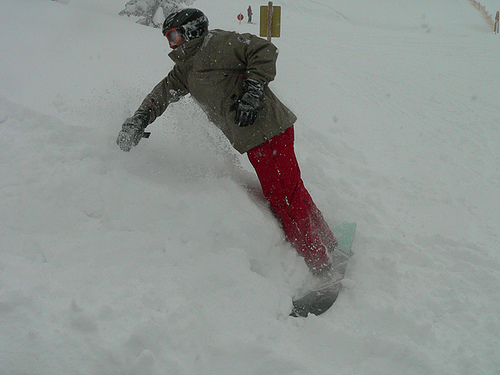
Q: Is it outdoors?
A: Yes, it is outdoors.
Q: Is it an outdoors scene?
A: Yes, it is outdoors.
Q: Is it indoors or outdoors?
A: It is outdoors.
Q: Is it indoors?
A: No, it is outdoors.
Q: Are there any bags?
A: No, there are no bags.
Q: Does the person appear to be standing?
A: Yes, the person is standing.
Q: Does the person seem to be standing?
A: Yes, the person is standing.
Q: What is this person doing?
A: The person is standing.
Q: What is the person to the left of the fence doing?
A: The person is standing.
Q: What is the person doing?
A: The person is standing.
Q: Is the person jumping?
A: No, the person is standing.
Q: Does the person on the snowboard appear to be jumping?
A: No, the person is standing.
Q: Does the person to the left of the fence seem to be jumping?
A: No, the person is standing.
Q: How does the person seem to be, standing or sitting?
A: The person is standing.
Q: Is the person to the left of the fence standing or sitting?
A: The person is standing.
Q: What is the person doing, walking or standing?
A: The person is standing.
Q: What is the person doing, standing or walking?
A: The person is standing.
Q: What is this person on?
A: The person is on the snow board.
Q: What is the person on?
A: The person is on the snow board.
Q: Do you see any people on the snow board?
A: Yes, there is a person on the snow board.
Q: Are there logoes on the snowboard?
A: No, there is a person on the snowboard.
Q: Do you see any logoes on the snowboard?
A: No, there is a person on the snowboard.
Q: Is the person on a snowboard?
A: Yes, the person is on a snowboard.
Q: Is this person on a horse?
A: No, the person is on a snowboard.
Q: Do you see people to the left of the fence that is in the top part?
A: Yes, there is a person to the left of the fence.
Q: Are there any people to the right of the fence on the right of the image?
A: No, the person is to the left of the fence.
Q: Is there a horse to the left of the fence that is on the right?
A: No, there is a person to the left of the fence.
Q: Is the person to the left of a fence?
A: Yes, the person is to the left of a fence.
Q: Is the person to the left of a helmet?
A: No, the person is to the left of a fence.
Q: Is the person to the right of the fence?
A: No, the person is to the left of the fence.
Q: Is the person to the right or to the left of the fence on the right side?
A: The person is to the left of the fence.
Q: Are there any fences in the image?
A: Yes, there is a fence.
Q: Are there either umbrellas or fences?
A: Yes, there is a fence.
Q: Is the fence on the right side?
A: Yes, the fence is on the right of the image.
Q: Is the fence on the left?
A: No, the fence is on the right of the image.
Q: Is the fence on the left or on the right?
A: The fence is on the right of the image.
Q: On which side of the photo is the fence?
A: The fence is on the right of the image.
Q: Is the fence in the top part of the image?
A: Yes, the fence is in the top of the image.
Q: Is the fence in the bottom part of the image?
A: No, the fence is in the top of the image.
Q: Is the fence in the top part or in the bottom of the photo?
A: The fence is in the top of the image.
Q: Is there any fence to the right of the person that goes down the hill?
A: Yes, there is a fence to the right of the person.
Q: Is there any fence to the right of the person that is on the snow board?
A: Yes, there is a fence to the right of the person.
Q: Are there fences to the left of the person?
A: No, the fence is to the right of the person.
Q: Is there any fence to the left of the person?
A: No, the fence is to the right of the person.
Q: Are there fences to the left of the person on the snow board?
A: No, the fence is to the right of the person.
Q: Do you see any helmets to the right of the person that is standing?
A: No, there is a fence to the right of the person.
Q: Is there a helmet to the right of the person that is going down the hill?
A: No, there is a fence to the right of the person.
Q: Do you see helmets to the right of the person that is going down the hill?
A: No, there is a fence to the right of the person.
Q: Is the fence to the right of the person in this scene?
A: Yes, the fence is to the right of the person.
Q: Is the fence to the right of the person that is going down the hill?
A: Yes, the fence is to the right of the person.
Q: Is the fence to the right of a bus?
A: No, the fence is to the right of the person.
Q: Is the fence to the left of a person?
A: No, the fence is to the right of a person.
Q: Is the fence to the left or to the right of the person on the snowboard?
A: The fence is to the right of the person.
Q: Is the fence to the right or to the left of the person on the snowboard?
A: The fence is to the right of the person.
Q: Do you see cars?
A: No, there are no cars.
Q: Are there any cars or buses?
A: No, there are no cars or buses.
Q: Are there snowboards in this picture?
A: Yes, there is a snowboard.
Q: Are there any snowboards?
A: Yes, there is a snowboard.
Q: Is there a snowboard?
A: Yes, there is a snowboard.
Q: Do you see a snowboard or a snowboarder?
A: Yes, there is a snowboard.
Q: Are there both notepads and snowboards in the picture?
A: No, there is a snowboard but no notepads.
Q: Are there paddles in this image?
A: No, there are no paddles.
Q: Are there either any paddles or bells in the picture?
A: No, there are no paddles or bells.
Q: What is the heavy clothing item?
A: The clothing item is a jacket.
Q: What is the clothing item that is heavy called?
A: The clothing item is a jacket.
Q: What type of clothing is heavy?
A: The clothing is a jacket.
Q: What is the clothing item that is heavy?
A: The clothing item is a jacket.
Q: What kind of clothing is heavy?
A: The clothing is a jacket.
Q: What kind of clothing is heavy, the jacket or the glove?
A: The jacket is heavy.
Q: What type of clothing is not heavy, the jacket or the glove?
A: The glove is not heavy.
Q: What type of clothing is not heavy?
A: The clothing is a glove.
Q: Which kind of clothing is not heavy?
A: The clothing is a glove.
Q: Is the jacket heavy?
A: Yes, the jacket is heavy.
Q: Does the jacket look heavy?
A: Yes, the jacket is heavy.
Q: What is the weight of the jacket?
A: The jacket is heavy.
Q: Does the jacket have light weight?
A: No, the jacket is heavy.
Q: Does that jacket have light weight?
A: No, the jacket is heavy.